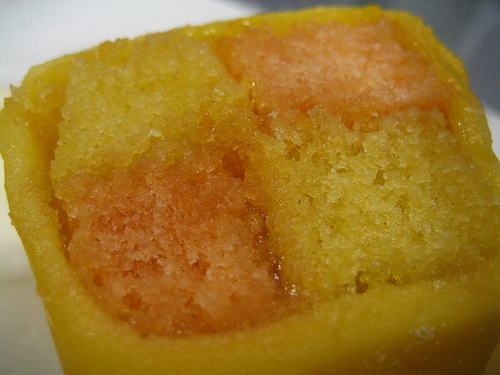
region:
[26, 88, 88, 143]
part of the yellow food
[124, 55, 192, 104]
part of the yellow food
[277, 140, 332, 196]
part of the yellow food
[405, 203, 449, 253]
part of the yellow food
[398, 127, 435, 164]
part of the yellow food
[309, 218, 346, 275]
part of the yellow food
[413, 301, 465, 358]
part of the yellow food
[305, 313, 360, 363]
part of the yellow food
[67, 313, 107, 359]
part of the yellow food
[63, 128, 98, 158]
part of the yellow food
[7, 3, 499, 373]
yellow and orange cake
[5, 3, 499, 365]
square moist yellow cake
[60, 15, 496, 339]
four square sections of cake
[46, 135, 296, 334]
lower left red section of cake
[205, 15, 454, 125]
upper right red section of cake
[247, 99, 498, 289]
lower right yellow section of cake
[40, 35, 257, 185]
upper right yellow section of cake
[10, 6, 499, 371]
moist yellow cake-like food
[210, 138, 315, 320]
separation area of sections of cake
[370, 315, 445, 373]
powdery white substance on cake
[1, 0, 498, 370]
the food has a checkered pattern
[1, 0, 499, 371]
the food has a square pattern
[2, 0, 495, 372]
the food is yellow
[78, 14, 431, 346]
the food has orange squares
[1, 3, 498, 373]
the food is in the shape of a square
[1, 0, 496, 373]
the photo is of food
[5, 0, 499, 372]
the plate is white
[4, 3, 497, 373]
the item is edible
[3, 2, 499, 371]
the food is made of cornmeal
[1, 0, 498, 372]
the food has a border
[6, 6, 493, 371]
Yellow square of corn bread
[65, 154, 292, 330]
Saturated bit of corn bread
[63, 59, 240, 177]
Section of a piece of corn bread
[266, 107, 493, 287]
Square section of a piece of cornbread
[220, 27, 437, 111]
Peach colored section of corn bread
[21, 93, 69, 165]
Hollow spot on corn bread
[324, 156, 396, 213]
Spongy pieces on corn bread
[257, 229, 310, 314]
Wet section of corn bread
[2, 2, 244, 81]
White table behind corn bread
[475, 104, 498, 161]
Edge of white plate near corn bread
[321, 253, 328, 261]
part of a white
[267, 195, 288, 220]
side of a meal